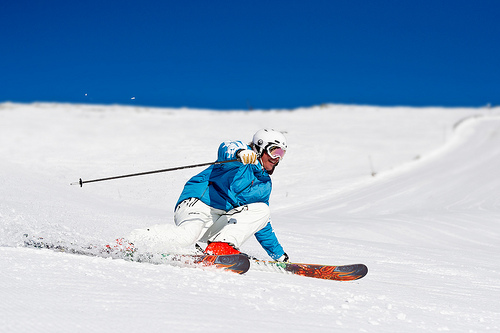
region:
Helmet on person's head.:
[251, 124, 293, 138]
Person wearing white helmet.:
[240, 116, 310, 151]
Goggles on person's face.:
[261, 137, 291, 172]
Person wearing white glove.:
[233, 145, 272, 185]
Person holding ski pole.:
[203, 143, 285, 188]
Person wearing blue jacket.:
[197, 145, 259, 194]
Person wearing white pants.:
[178, 174, 249, 250]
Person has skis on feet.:
[141, 226, 336, 306]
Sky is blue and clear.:
[183, 35, 271, 92]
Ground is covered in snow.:
[316, 131, 445, 239]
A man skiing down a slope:
[53, 119, 393, 291]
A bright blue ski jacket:
[158, 120, 275, 207]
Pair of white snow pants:
[171, 196, 255, 266]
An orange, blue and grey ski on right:
[250, 242, 360, 278]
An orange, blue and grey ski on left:
[120, 246, 260, 276]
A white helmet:
[250, 111, 290, 158]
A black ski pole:
[55, 157, 221, 187]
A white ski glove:
[230, 141, 255, 161]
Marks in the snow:
[325, 91, 497, 211]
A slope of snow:
[42, 82, 447, 272]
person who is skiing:
[37, 109, 412, 302]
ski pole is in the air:
[62, 151, 248, 199]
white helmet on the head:
[247, 130, 290, 155]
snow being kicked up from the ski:
[8, 221, 226, 271]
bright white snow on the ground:
[4, 98, 499, 330]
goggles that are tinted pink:
[267, 143, 285, 158]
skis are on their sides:
[17, 230, 372, 284]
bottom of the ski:
[286, 257, 373, 285]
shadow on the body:
[200, 164, 244, 241]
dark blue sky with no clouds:
[1, 0, 499, 110]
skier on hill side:
[75, 109, 357, 291]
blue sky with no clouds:
[14, 25, 47, 63]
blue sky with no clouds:
[64, 20, 107, 55]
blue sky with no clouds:
[212, 30, 252, 82]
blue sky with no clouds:
[402, 25, 432, 67]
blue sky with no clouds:
[141, 32, 202, 87]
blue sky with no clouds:
[231, 5, 271, 58]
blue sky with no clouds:
[288, 5, 348, 75]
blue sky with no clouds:
[143, 20, 198, 60]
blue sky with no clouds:
[183, 3, 236, 75]